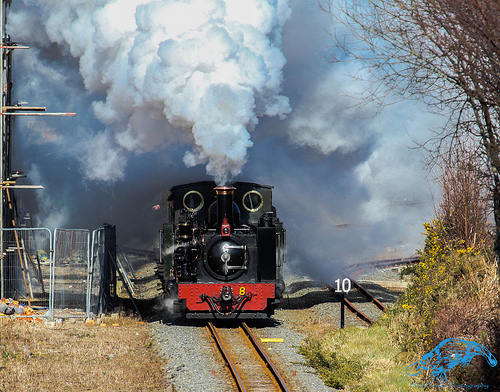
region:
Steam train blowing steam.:
[0, 1, 496, 322]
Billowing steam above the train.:
[6, 7, 496, 285]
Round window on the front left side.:
[176, 186, 208, 214]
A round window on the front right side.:
[239, 188, 266, 213]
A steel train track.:
[200, 320, 300, 386]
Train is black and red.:
[156, 175, 278, 316]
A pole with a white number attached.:
[330, 270, 355, 330]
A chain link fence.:
[0, 225, 100, 320]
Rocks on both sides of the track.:
[145, 315, 335, 390]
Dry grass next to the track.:
[1, 310, 169, 390]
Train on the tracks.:
[152, 176, 290, 325]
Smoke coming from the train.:
[10, 2, 447, 277]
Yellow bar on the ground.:
[258, 334, 285, 344]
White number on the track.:
[330, 278, 351, 297]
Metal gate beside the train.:
[47, 221, 100, 319]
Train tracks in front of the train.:
[205, 320, 285, 390]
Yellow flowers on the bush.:
[376, 219, 479, 349]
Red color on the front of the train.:
[177, 282, 277, 311]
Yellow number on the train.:
[236, 283, 250, 298]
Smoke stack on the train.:
[213, 181, 238, 228]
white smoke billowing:
[1, 0, 291, 187]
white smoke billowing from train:
[10, 0, 293, 322]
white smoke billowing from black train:
[0, 3, 285, 325]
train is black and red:
[155, 179, 290, 325]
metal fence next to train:
[0, 175, 285, 332]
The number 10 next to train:
[124, 164, 356, 334]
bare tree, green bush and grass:
[318, 0, 497, 388]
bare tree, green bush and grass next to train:
[145, 0, 498, 390]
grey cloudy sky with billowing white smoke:
[0, 0, 493, 275]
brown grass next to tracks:
[0, 311, 292, 388]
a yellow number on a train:
[238, 283, 245, 296]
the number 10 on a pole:
[331, 276, 350, 329]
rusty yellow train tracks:
[205, 317, 280, 389]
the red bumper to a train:
[175, 281, 272, 313]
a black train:
[168, 180, 276, 283]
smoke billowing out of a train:
[55, 0, 287, 185]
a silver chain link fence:
[3, 226, 127, 313]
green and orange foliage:
[385, 182, 492, 389]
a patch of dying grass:
[1, 318, 145, 385]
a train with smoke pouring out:
[158, 0, 273, 312]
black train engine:
[143, 162, 285, 316]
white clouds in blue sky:
[50, 18, 101, 40]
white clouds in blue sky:
[32, 128, 82, 163]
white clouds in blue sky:
[112, 131, 144, 166]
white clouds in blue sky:
[89, 159, 140, 192]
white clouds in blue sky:
[148, 49, 186, 80]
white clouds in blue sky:
[199, 26, 262, 83]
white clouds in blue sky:
[272, 84, 346, 150]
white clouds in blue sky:
[286, 91, 350, 124]